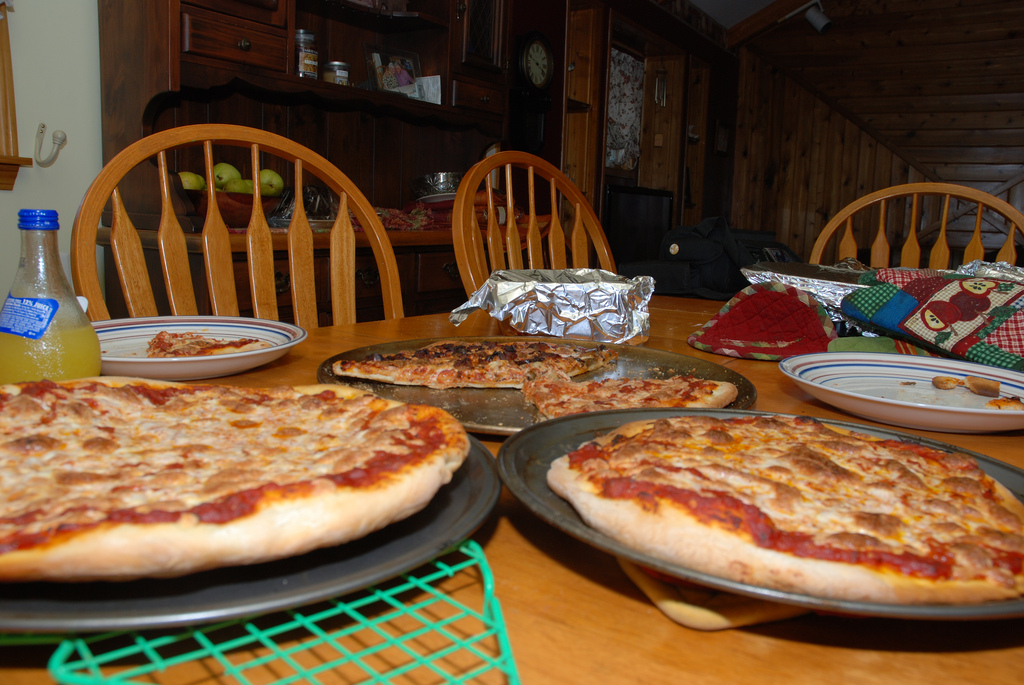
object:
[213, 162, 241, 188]
apple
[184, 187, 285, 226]
bowl